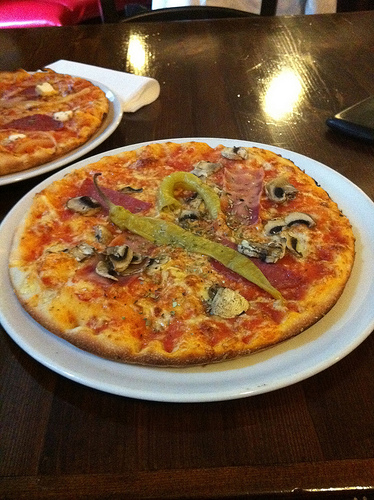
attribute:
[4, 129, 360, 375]
pizza — whole, large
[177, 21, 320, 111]
table — wood, dark, brown, wooden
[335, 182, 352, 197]
plate — white, round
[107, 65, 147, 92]
napkin — white, folded 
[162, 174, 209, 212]
pepper — green, long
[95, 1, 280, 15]
chair — wooden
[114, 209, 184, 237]
pepper — long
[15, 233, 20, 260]
crust — thin